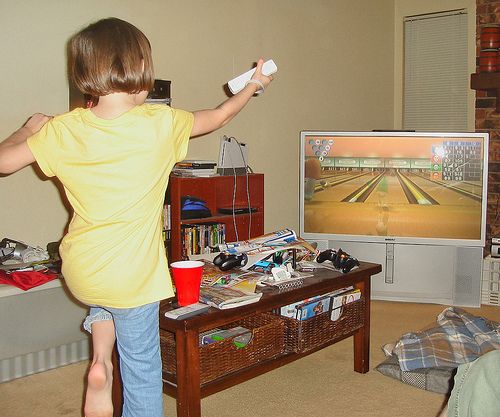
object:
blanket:
[381, 307, 499, 373]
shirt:
[25, 102, 195, 309]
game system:
[217, 135, 249, 176]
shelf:
[170, 169, 265, 181]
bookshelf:
[170, 172, 264, 262]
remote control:
[164, 303, 211, 321]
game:
[303, 136, 484, 240]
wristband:
[246, 79, 264, 91]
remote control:
[213, 248, 248, 271]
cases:
[272, 285, 362, 321]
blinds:
[402, 14, 468, 133]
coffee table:
[110, 260, 381, 417]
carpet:
[0, 301, 500, 415]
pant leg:
[112, 301, 162, 416]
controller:
[316, 248, 360, 274]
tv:
[299, 130, 489, 247]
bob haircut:
[65, 17, 155, 98]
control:
[227, 59, 278, 95]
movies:
[301, 297, 331, 321]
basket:
[266, 297, 365, 355]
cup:
[170, 261, 205, 307]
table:
[158, 242, 377, 293]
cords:
[228, 137, 252, 242]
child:
[0, 17, 275, 417]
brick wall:
[470, 0, 499, 254]